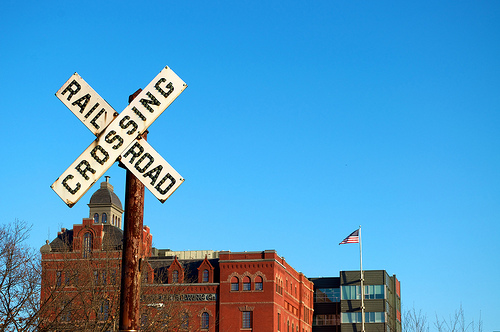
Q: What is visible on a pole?
A: A flag.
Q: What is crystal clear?
A: The sky.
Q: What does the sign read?
A: Railroad Crossing.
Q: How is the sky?
A: Bright blue with no clouds.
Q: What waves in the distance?
A: An American flag.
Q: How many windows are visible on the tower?
A: Five windows.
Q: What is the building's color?
A: Red brick.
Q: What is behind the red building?
A: A brown building.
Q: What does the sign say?
A: Railroad crossing.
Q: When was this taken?
A: Daytime.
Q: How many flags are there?
A: 1.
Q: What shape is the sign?
A: X.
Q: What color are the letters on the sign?
A: Black.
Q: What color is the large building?
A: Red.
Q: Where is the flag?
A: Next to the building.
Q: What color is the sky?
A: Blue.